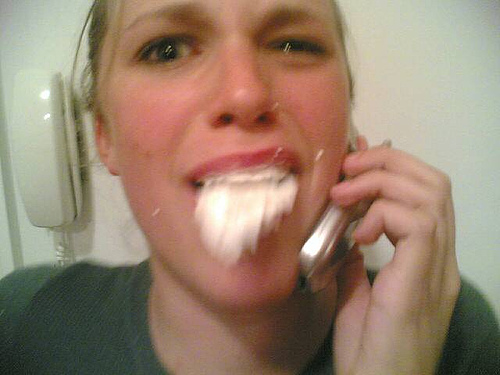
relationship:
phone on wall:
[1, 66, 95, 233] [4, 4, 498, 329]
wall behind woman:
[4, 4, 498, 329] [1, 1, 496, 373]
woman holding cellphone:
[1, 1, 496, 373] [297, 99, 371, 296]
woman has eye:
[44, 2, 408, 330] [137, 39, 197, 65]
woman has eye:
[44, 2, 408, 330] [271, 37, 327, 57]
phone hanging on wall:
[301, 119, 397, 296] [4, 4, 498, 329]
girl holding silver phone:
[1, 0, 499, 373] [297, 138, 396, 295]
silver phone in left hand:
[297, 138, 396, 295] [327, 144, 462, 374]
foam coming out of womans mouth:
[192, 175, 299, 262] [180, 145, 303, 205]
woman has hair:
[1, 1, 496, 373] [67, 0, 348, 161]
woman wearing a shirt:
[1, 1, 496, 373] [4, 263, 494, 373]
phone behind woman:
[14, 69, 87, 264] [1, 1, 496, 373]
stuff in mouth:
[207, 179, 280, 241] [180, 145, 303, 205]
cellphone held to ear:
[275, 116, 423, 311] [338, 69, 362, 142]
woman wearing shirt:
[1, 1, 496, 373] [50, 260, 476, 371]